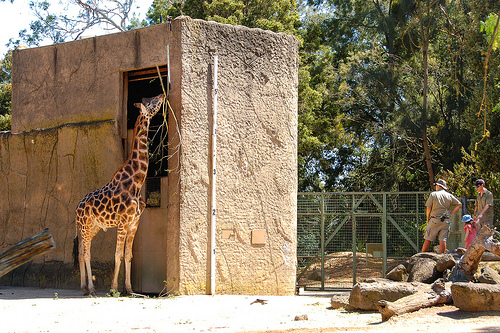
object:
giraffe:
[75, 94, 168, 298]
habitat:
[0, 14, 434, 332]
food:
[163, 96, 172, 105]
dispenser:
[161, 90, 173, 109]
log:
[379, 286, 452, 320]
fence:
[297, 191, 499, 290]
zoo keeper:
[422, 180, 462, 253]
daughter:
[465, 215, 479, 249]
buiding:
[11, 15, 301, 300]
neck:
[129, 115, 149, 191]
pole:
[211, 51, 217, 297]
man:
[423, 179, 461, 254]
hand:
[427, 215, 430, 221]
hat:
[462, 216, 472, 222]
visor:
[473, 179, 486, 187]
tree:
[149, 0, 351, 189]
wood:
[374, 279, 451, 319]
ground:
[1, 284, 499, 332]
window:
[124, 68, 168, 207]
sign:
[368, 242, 383, 258]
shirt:
[465, 224, 479, 250]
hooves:
[112, 290, 120, 297]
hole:
[358, 203, 364, 211]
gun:
[442, 216, 448, 225]